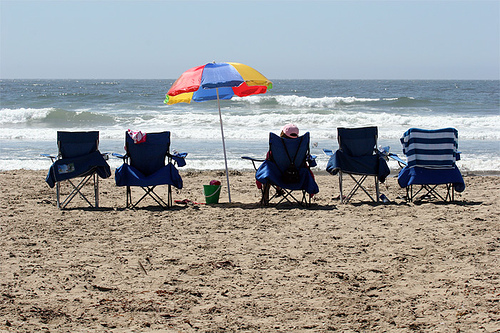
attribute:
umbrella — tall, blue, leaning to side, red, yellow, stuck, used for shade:
[162, 59, 273, 205]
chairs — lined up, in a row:
[45, 130, 468, 209]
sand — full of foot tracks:
[1, 168, 500, 330]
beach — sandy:
[2, 0, 499, 332]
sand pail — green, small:
[201, 181, 223, 206]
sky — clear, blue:
[2, 0, 499, 81]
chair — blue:
[48, 130, 113, 209]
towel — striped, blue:
[399, 125, 462, 171]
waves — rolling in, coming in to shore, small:
[2, 103, 500, 140]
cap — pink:
[283, 123, 301, 140]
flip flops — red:
[174, 196, 206, 207]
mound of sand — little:
[185, 164, 239, 177]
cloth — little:
[125, 126, 148, 146]